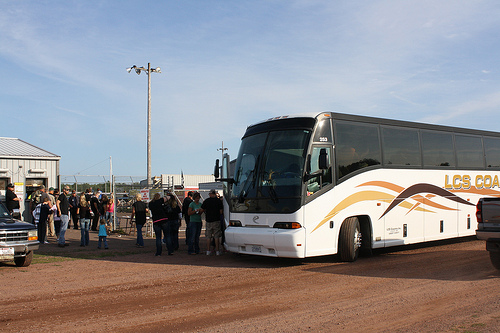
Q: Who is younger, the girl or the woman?
A: The girl is younger than the woman.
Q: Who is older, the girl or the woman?
A: The woman is older than the girl.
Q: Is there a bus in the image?
A: Yes, there is a bus.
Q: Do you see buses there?
A: Yes, there is a bus.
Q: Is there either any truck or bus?
A: Yes, there is a bus.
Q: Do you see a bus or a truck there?
A: Yes, there is a bus.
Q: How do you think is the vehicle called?
A: The vehicle is a bus.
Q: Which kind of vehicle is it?
A: The vehicle is a bus.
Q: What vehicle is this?
A: This is a bus.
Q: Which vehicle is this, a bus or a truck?
A: This is a bus.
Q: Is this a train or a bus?
A: This is a bus.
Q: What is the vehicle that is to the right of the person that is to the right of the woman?
A: The vehicle is a bus.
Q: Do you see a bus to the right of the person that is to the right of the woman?
A: Yes, there is a bus to the right of the person.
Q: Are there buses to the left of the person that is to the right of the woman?
A: No, the bus is to the right of the person.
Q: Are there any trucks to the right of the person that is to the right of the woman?
A: No, there is a bus to the right of the person.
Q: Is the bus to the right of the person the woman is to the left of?
A: Yes, the bus is to the right of the person.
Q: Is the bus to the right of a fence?
A: No, the bus is to the right of the person.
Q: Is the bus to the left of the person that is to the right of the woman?
A: No, the bus is to the right of the person.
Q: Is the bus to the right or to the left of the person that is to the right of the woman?
A: The bus is to the right of the person.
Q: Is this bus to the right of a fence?
A: No, the bus is to the right of the person.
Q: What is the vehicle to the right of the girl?
A: The vehicle is a bus.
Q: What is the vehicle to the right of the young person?
A: The vehicle is a bus.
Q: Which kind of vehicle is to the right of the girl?
A: The vehicle is a bus.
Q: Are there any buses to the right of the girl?
A: Yes, there is a bus to the right of the girl.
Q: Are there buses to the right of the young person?
A: Yes, there is a bus to the right of the girl.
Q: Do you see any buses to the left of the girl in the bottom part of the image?
A: No, the bus is to the right of the girl.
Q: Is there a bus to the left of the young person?
A: No, the bus is to the right of the girl.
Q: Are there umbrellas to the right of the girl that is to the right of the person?
A: No, there is a bus to the right of the girl.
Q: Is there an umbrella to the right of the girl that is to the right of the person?
A: No, there is a bus to the right of the girl.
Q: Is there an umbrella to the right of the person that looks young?
A: No, there is a bus to the right of the girl.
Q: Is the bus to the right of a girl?
A: Yes, the bus is to the right of a girl.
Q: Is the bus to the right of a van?
A: No, the bus is to the right of a girl.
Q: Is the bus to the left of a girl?
A: No, the bus is to the right of a girl.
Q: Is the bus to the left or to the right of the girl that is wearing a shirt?
A: The bus is to the right of the girl.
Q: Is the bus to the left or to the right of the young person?
A: The bus is to the right of the girl.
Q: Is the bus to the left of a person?
A: No, the bus is to the right of a person.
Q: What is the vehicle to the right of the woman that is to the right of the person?
A: The vehicle is a bus.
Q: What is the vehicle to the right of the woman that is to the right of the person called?
A: The vehicle is a bus.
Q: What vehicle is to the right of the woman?
A: The vehicle is a bus.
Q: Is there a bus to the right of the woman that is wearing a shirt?
A: Yes, there is a bus to the right of the woman.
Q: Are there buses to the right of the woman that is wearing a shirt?
A: Yes, there is a bus to the right of the woman.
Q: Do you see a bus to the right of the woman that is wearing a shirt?
A: Yes, there is a bus to the right of the woman.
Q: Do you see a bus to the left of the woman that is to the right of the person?
A: No, the bus is to the right of the woman.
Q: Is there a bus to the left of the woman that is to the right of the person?
A: No, the bus is to the right of the woman.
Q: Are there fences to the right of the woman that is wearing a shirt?
A: No, there is a bus to the right of the woman.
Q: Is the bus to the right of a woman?
A: Yes, the bus is to the right of a woman.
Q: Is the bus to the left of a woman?
A: No, the bus is to the right of a woman.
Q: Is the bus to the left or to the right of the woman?
A: The bus is to the right of the woman.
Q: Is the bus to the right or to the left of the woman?
A: The bus is to the right of the woman.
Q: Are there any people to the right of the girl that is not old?
A: Yes, there is a person to the right of the girl.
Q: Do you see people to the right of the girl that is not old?
A: Yes, there is a person to the right of the girl.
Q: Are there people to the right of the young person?
A: Yes, there is a person to the right of the girl.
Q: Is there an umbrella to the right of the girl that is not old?
A: No, there is a person to the right of the girl.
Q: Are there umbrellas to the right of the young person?
A: No, there is a person to the right of the girl.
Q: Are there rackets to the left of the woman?
A: No, there is a person to the left of the woman.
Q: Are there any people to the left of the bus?
A: Yes, there is a person to the left of the bus.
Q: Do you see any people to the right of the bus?
A: No, the person is to the left of the bus.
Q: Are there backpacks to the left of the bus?
A: No, there is a person to the left of the bus.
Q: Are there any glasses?
A: No, there are no glasses.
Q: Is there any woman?
A: Yes, there is a woman.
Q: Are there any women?
A: Yes, there is a woman.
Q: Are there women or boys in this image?
A: Yes, there is a woman.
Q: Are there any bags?
A: No, there are no bags.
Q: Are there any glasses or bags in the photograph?
A: No, there are no bags or glasses.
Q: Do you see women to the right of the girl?
A: Yes, there is a woman to the right of the girl.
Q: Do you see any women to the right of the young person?
A: Yes, there is a woman to the right of the girl.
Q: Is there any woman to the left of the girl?
A: No, the woman is to the right of the girl.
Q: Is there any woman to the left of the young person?
A: No, the woman is to the right of the girl.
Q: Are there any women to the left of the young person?
A: No, the woman is to the right of the girl.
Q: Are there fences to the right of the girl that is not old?
A: No, there is a woman to the right of the girl.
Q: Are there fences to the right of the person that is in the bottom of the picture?
A: No, there is a woman to the right of the girl.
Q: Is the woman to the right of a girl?
A: Yes, the woman is to the right of a girl.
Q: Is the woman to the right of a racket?
A: No, the woman is to the right of a girl.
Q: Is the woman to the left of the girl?
A: No, the woman is to the right of the girl.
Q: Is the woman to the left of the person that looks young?
A: No, the woman is to the right of the girl.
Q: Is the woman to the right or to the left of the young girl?
A: The woman is to the right of the girl.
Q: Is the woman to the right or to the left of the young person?
A: The woman is to the right of the girl.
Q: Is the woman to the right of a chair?
A: No, the woman is to the right of the person.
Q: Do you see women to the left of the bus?
A: Yes, there is a woman to the left of the bus.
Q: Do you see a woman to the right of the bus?
A: No, the woman is to the left of the bus.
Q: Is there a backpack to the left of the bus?
A: No, there is a woman to the left of the bus.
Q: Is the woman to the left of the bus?
A: Yes, the woman is to the left of the bus.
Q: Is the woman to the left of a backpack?
A: No, the woman is to the left of the bus.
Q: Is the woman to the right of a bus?
A: No, the woman is to the left of a bus.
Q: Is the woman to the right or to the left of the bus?
A: The woman is to the left of the bus.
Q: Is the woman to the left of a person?
A: Yes, the woman is to the left of a person.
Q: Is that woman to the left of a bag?
A: No, the woman is to the left of a person.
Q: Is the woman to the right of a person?
A: No, the woman is to the left of a person.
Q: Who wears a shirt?
A: The woman wears a shirt.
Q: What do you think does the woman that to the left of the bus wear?
A: The woman wears a shirt.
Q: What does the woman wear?
A: The woman wears a shirt.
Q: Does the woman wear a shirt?
A: Yes, the woman wears a shirt.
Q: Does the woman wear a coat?
A: No, the woman wears a shirt.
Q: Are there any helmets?
A: No, there are no helmets.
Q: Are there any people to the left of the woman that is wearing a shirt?
A: Yes, there is a person to the left of the woman.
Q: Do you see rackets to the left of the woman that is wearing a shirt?
A: No, there is a person to the left of the woman.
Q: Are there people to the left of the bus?
A: Yes, there is a person to the left of the bus.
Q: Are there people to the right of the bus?
A: No, the person is to the left of the bus.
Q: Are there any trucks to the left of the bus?
A: No, there is a person to the left of the bus.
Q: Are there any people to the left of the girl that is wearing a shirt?
A: Yes, there is a person to the left of the girl.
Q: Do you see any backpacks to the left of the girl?
A: No, there is a person to the left of the girl.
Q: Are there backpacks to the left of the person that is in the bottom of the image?
A: No, there is a person to the left of the girl.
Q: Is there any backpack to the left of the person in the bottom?
A: No, there is a person to the left of the girl.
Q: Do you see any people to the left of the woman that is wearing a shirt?
A: Yes, there is a person to the left of the woman.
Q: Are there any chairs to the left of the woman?
A: No, there is a person to the left of the woman.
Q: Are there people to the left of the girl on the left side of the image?
A: Yes, there is a person to the left of the girl.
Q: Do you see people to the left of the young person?
A: Yes, there is a person to the left of the girl.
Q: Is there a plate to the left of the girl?
A: No, there is a person to the left of the girl.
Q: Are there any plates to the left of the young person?
A: No, there is a person to the left of the girl.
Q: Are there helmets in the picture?
A: No, there are no helmets.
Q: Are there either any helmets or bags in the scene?
A: No, there are no helmets or bags.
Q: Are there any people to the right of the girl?
A: Yes, there is a person to the right of the girl.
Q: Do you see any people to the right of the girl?
A: Yes, there is a person to the right of the girl.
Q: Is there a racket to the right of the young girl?
A: No, there is a person to the right of the girl.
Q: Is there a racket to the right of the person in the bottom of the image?
A: No, there is a person to the right of the girl.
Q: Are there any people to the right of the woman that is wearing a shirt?
A: Yes, there is a person to the right of the woman.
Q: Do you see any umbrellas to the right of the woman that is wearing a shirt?
A: No, there is a person to the right of the woman.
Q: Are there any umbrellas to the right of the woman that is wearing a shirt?
A: No, there is a person to the right of the woman.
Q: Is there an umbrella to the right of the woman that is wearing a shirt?
A: No, there is a person to the right of the woman.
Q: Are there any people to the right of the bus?
A: No, the person is to the left of the bus.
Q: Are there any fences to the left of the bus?
A: No, there is a person to the left of the bus.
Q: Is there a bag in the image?
A: No, there are no bags.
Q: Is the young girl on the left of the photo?
A: Yes, the girl is on the left of the image.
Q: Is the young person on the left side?
A: Yes, the girl is on the left of the image.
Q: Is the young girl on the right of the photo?
A: No, the girl is on the left of the image.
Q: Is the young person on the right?
A: No, the girl is on the left of the image.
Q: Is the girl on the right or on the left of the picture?
A: The girl is on the left of the image.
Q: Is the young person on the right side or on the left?
A: The girl is on the left of the image.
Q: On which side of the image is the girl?
A: The girl is on the left of the image.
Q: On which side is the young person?
A: The girl is on the left of the image.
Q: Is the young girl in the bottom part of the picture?
A: Yes, the girl is in the bottom of the image.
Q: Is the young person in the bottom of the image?
A: Yes, the girl is in the bottom of the image.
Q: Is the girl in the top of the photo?
A: No, the girl is in the bottom of the image.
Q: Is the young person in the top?
A: No, the girl is in the bottom of the image.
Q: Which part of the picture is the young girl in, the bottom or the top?
A: The girl is in the bottom of the image.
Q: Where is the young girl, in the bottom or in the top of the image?
A: The girl is in the bottom of the image.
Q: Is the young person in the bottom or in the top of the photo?
A: The girl is in the bottom of the image.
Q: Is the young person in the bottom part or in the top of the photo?
A: The girl is in the bottom of the image.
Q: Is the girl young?
A: Yes, the girl is young.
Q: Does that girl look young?
A: Yes, the girl is young.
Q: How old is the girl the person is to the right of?
A: The girl is young.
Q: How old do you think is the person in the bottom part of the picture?
A: The girl is young.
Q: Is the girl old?
A: No, the girl is young.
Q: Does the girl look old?
A: No, the girl is young.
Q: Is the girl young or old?
A: The girl is young.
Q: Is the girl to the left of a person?
A: No, the girl is to the right of a person.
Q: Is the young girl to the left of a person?
A: Yes, the girl is to the left of a person.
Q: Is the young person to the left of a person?
A: Yes, the girl is to the left of a person.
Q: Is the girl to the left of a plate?
A: No, the girl is to the left of a person.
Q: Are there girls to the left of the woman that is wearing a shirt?
A: Yes, there is a girl to the left of the woman.